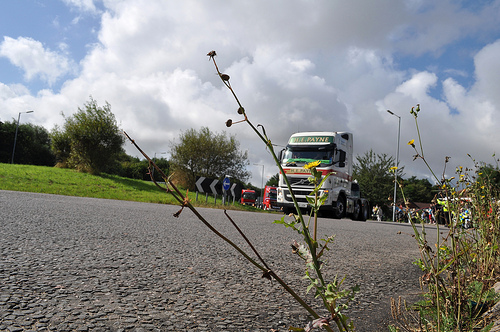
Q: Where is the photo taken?
A: On a street.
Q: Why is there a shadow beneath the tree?
A: It is sunny.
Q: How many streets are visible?
A: One.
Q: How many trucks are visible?
A: One.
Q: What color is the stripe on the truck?
A: Red.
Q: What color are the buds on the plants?
A: Yellow.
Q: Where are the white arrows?
A: In front of the truck.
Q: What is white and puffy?
A: Clouds.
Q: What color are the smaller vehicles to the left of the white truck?
A: Red.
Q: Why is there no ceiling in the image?
A: It is taken outdoors.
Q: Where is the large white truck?
A: On the road.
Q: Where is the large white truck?
A: On the road.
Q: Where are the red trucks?
A: Behind the white truck.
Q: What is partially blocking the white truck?
A: Wildflowers.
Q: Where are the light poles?
A: Alongside the road.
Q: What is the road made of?
A: Asphalt.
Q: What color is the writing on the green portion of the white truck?
A: Yellow.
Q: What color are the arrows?
A: White.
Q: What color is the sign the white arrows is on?
A: Black.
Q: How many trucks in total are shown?
A: 3.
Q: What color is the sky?
A: Blue.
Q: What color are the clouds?
A: White.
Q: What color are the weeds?
A: Green.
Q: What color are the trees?
A: Green.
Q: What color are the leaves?
A: Green.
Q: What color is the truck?
A: White.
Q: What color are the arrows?
A: White.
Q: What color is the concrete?
A: Gray.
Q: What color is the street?
A: Gray.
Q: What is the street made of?
A: Asphalt.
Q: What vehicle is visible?
A: Cab of semi-truck.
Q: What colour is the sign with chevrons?
A: Black and white.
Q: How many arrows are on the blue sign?
A: 1.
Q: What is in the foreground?
A: Yellow flowers.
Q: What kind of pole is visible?
A: Light pole.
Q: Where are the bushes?
A: On the grassy knoll.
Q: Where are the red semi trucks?
A: Behind the white semi truck.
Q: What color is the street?
A: The street is grey.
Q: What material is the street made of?
A: The street is made of concrete.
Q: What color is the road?
A: Black.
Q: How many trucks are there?
A: Three.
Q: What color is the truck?
A: White.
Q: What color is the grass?
A: Green.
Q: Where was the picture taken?
A: Next to the road.